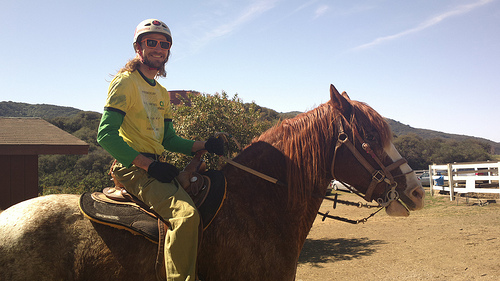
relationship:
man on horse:
[93, 14, 237, 280] [2, 80, 431, 280]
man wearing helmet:
[93, 14, 237, 280] [132, 13, 176, 48]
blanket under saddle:
[77, 206, 221, 248] [81, 176, 223, 208]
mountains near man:
[6, 81, 300, 120] [93, 14, 237, 280]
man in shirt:
[93, 14, 237, 280] [101, 69, 176, 156]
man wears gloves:
[93, 14, 237, 280] [136, 136, 230, 180]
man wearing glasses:
[93, 14, 237, 280] [141, 38, 173, 52]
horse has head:
[2, 80, 431, 280] [316, 81, 444, 222]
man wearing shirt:
[93, 14, 237, 280] [101, 69, 176, 156]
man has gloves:
[93, 14, 237, 280] [136, 136, 230, 180]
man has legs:
[93, 14, 237, 280] [114, 171, 236, 277]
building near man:
[1, 114, 86, 195] [93, 14, 237, 280]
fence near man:
[421, 156, 499, 206] [93, 14, 237, 280]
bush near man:
[164, 84, 265, 171] [93, 14, 237, 280]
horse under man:
[2, 80, 431, 280] [93, 14, 237, 280]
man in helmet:
[93, 14, 237, 280] [132, 13, 176, 48]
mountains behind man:
[6, 81, 300, 120] [93, 14, 237, 280]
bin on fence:
[431, 175, 446, 186] [421, 156, 499, 206]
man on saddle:
[93, 14, 237, 280] [81, 176, 223, 208]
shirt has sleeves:
[101, 69, 176, 156] [100, 102, 201, 156]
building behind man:
[1, 114, 86, 195] [93, 14, 237, 280]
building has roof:
[1, 114, 86, 195] [0, 113, 92, 157]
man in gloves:
[93, 14, 237, 280] [136, 136, 230, 180]